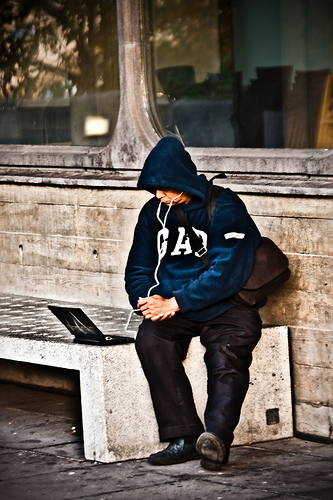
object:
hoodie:
[123, 136, 259, 324]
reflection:
[0, 9, 118, 100]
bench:
[0, 291, 295, 463]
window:
[141, 2, 327, 158]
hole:
[92, 250, 97, 257]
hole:
[19, 244, 22, 250]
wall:
[0, 177, 331, 437]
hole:
[265, 408, 279, 425]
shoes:
[147, 435, 204, 466]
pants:
[134, 284, 261, 443]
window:
[0, 0, 120, 149]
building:
[0, 1, 331, 444]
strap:
[167, 206, 210, 269]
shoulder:
[205, 184, 254, 222]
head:
[155, 139, 196, 206]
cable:
[124, 194, 185, 329]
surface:
[0, 294, 58, 340]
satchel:
[175, 206, 291, 308]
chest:
[155, 207, 207, 266]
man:
[123, 137, 289, 471]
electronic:
[47, 303, 135, 346]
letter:
[156, 227, 169, 258]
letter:
[170, 225, 192, 256]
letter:
[191, 223, 209, 256]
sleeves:
[172, 284, 191, 314]